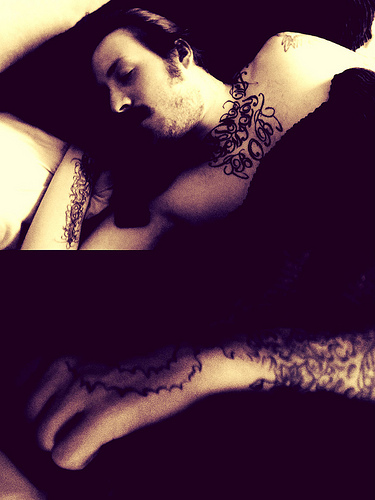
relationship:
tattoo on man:
[213, 90, 280, 180] [30, 10, 371, 224]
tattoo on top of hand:
[61, 340, 228, 404] [28, 330, 270, 471]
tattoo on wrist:
[65, 155, 91, 243] [45, 132, 104, 252]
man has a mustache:
[30, 10, 371, 224] [117, 105, 157, 129]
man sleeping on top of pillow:
[30, 10, 371, 224] [37, 47, 90, 124]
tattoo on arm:
[65, 155, 91, 243] [28, 153, 84, 255]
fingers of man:
[23, 373, 103, 472] [30, 10, 371, 224]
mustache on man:
[117, 105, 157, 129] [30, 10, 371, 224]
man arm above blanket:
[30, 10, 371, 224] [180, 411, 357, 495]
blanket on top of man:
[276, 145, 373, 245] [30, 10, 371, 224]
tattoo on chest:
[213, 90, 280, 180] [192, 71, 326, 227]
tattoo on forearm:
[65, 155, 91, 243] [28, 153, 84, 255]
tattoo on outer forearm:
[245, 321, 374, 398] [216, 307, 369, 434]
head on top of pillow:
[79, 18, 202, 137] [37, 47, 90, 124]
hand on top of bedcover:
[28, 330, 270, 471] [153, 421, 248, 487]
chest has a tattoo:
[192, 71, 326, 227] [213, 90, 280, 180]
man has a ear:
[30, 10, 371, 224] [172, 37, 193, 71]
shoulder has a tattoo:
[260, 31, 337, 73] [274, 27, 292, 50]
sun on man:
[308, 36, 350, 78] [30, 10, 371, 224]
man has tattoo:
[30, 10, 371, 224] [213, 90, 280, 180]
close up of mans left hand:
[0, 248, 373, 491] [28, 330, 270, 471]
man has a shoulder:
[30, 10, 371, 224] [247, 31, 325, 74]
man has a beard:
[30, 10, 371, 224] [153, 80, 187, 142]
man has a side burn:
[30, 10, 371, 224] [158, 62, 185, 82]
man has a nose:
[30, 10, 371, 224] [110, 89, 130, 114]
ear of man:
[170, 41, 196, 65] [30, 10, 371, 224]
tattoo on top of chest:
[213, 90, 280, 180] [192, 71, 326, 227]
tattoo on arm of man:
[65, 155, 91, 243] [30, 10, 371, 224]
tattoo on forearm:
[245, 321, 374, 398] [216, 307, 369, 434]